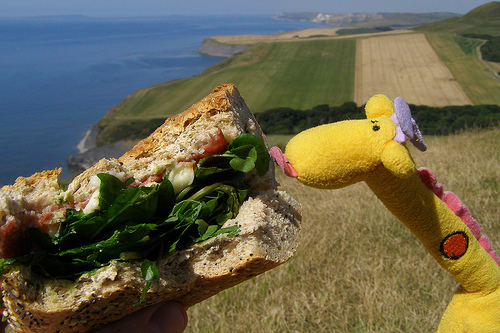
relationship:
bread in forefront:
[0, 82, 303, 333] [3, 76, 499, 328]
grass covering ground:
[184, 133, 496, 330] [166, 126, 497, 330]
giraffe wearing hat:
[257, 89, 497, 331] [387, 86, 430, 153]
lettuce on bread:
[20, 159, 253, 281] [0, 82, 303, 333]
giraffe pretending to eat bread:
[266, 93, 500, 332] [0, 82, 303, 333]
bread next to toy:
[0, 82, 303, 333] [272, 88, 497, 330]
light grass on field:
[314, 239, 418, 309] [177, 130, 497, 331]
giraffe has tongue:
[266, 93, 500, 332] [267, 141, 298, 182]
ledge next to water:
[193, 32, 247, 64] [0, 9, 341, 200]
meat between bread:
[0, 128, 230, 258] [0, 82, 302, 331]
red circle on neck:
[438, 229, 469, 263] [402, 170, 480, 278]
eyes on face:
[367, 116, 379, 131] [274, 108, 394, 187]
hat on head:
[393, 96, 428, 152] [365, 88, 423, 184]